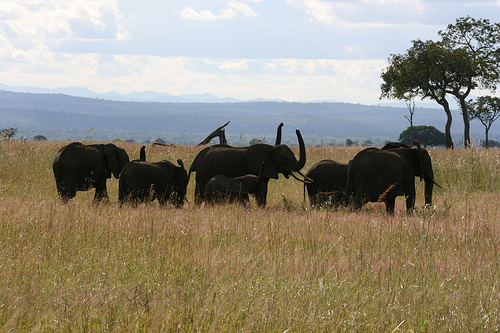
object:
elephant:
[344, 140, 443, 218]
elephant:
[53, 141, 146, 206]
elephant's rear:
[53, 149, 79, 198]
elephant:
[190, 129, 314, 208]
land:
[1, 91, 496, 149]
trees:
[396, 124, 453, 148]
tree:
[196, 121, 236, 146]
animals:
[53, 142, 146, 207]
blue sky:
[263, 48, 333, 87]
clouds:
[1, 1, 493, 102]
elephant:
[118, 158, 188, 210]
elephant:
[205, 161, 267, 210]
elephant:
[303, 160, 349, 211]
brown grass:
[0, 139, 499, 330]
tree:
[377, 14, 500, 149]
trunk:
[295, 129, 306, 171]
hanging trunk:
[417, 164, 452, 206]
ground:
[5, 193, 497, 320]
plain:
[0, 140, 499, 331]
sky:
[1, 1, 499, 101]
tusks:
[289, 171, 315, 184]